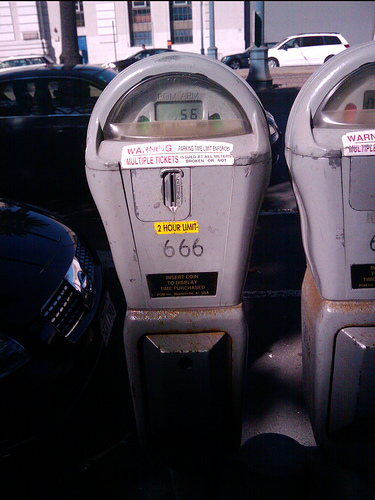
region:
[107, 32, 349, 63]
these are some cars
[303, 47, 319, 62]
the car is white in color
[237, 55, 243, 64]
the car is black in color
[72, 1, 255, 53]
this is a building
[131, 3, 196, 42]
these are some windows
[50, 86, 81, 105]
this is a window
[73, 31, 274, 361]
this is a parking booth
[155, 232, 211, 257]
these are three numbers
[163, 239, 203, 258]
Three numbers on a parking meter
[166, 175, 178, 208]
Coin slot on a parking meter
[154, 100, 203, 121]
Numbers on a parking meter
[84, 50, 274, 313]
Top of a parking meter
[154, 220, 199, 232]
A sticker on a parking meter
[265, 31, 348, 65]
White van on the road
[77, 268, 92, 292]
Emblem on the front of a car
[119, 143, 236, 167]
Warning stickers on a parking meter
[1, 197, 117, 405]
Front end of a dark car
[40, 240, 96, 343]
Front grill of a dark car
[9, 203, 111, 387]
a car is parked near the ticket machine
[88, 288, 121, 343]
number plate of the car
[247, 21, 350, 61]
white color parked near the road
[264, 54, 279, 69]
wheel of the car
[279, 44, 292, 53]
side mirror of the car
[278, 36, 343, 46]
window of the car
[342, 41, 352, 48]
red color indicator of the car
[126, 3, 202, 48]
window of the building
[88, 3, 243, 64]
two windows on building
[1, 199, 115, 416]
front of parked car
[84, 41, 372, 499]
two gray parking meters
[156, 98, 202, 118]
digital display on meter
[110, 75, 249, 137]
clear cover over display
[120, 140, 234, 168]
red words on label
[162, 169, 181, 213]
coin slot of meter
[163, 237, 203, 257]
three black numbers on gray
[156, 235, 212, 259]
666 is on the parking meter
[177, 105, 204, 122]
56 is on the meter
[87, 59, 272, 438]
the parking meter is mettalic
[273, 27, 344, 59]
the car is white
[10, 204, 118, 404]
the car is blue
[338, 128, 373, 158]
the white sticker says warning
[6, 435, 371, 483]
the bottom photo is black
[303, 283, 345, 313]
rust is on the meter